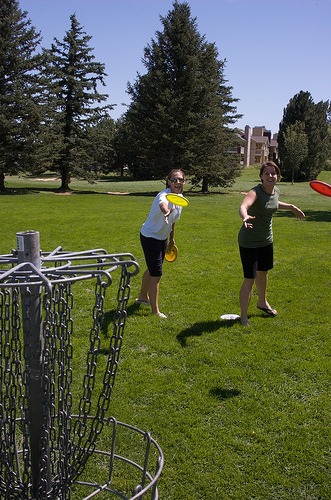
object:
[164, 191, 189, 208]
frisbees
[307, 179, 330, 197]
frisbee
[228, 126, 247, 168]
houses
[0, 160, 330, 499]
field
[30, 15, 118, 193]
pine tree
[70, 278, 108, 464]
chain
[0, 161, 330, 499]
grass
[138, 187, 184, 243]
shirt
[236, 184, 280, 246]
shirt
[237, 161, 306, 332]
person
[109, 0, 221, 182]
tree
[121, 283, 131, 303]
chain link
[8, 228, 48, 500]
pole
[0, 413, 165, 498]
basket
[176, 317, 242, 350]
shadow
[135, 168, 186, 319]
woman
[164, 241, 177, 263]
frisbee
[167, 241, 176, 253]
hand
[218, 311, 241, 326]
frisbee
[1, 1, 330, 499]
background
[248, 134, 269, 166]
building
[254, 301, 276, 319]
shoe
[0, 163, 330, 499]
ground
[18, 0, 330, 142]
sky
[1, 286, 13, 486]
chain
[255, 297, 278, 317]
foot